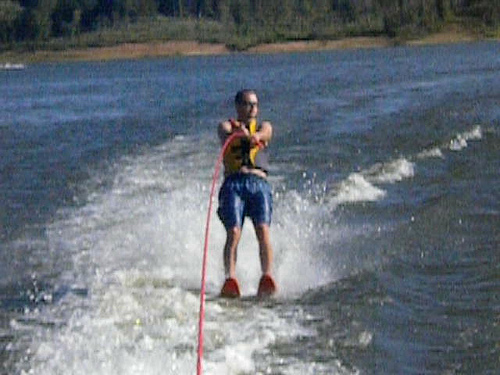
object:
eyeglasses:
[238, 99, 263, 108]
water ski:
[256, 273, 277, 295]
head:
[233, 85, 259, 123]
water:
[0, 38, 498, 374]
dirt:
[60, 39, 388, 62]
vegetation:
[0, 1, 499, 54]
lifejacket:
[215, 113, 277, 178]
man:
[214, 88, 274, 295]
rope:
[193, 130, 242, 374]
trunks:
[212, 174, 274, 228]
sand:
[82, 42, 221, 55]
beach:
[0, 24, 499, 64]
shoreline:
[0, 31, 499, 66]